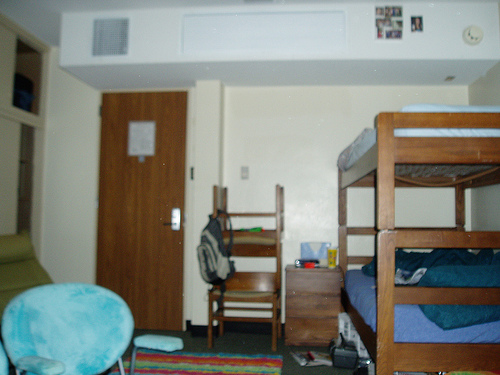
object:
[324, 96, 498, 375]
bunkbed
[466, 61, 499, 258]
wall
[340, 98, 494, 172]
bedding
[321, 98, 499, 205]
upper bunk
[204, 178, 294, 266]
chair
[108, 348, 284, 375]
rug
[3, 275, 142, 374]
chair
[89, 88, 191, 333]
door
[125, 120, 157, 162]
sign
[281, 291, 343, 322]
drawers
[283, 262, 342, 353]
night table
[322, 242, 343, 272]
item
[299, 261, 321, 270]
item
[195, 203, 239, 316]
backpack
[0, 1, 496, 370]
room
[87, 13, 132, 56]
vent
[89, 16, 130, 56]
air conditioner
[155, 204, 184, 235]
door knob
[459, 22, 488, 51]
fire alarm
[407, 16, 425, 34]
pictures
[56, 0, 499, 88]
wall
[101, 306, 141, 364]
arm rest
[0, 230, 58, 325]
chair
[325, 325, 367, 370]
box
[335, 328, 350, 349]
handle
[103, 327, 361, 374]
floor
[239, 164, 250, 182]
outlet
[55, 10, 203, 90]
soffit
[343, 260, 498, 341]
bedding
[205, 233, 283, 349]
chair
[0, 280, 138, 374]
material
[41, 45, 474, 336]
wall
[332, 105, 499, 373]
frame